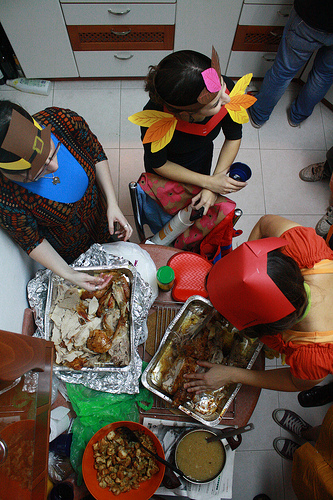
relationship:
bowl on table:
[80, 422, 164, 498] [17, 243, 264, 498]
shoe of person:
[271, 434, 298, 458] [266, 403, 322, 496]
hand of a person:
[181, 359, 232, 395] [176, 212, 317, 396]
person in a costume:
[136, 48, 249, 217] [126, 43, 256, 154]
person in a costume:
[0, 95, 131, 291] [0, 105, 107, 252]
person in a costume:
[176, 212, 317, 396] [204, 225, 321, 383]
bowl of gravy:
[170, 428, 225, 483] [175, 431, 223, 479]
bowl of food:
[80, 422, 164, 498] [96, 430, 143, 485]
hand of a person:
[104, 205, 132, 240] [0, 95, 131, 291]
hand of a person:
[69, 271, 115, 292] [0, 95, 131, 291]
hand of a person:
[207, 166, 248, 193] [136, 48, 249, 217]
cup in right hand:
[214, 158, 263, 176] [205, 166, 246, 195]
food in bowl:
[101, 440, 141, 481] [80, 422, 164, 498]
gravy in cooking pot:
[175, 431, 223, 479] [171, 419, 255, 480]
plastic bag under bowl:
[70, 382, 143, 422] [85, 429, 163, 498]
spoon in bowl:
[114, 425, 183, 477] [80, 422, 164, 498]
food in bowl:
[98, 431, 157, 484] [80, 417, 168, 492]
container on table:
[156, 265, 176, 291] [23, 240, 267, 447]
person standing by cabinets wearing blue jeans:
[253, 6, 323, 122] [254, 10, 322, 120]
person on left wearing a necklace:
[0, 95, 131, 291] [42, 167, 65, 186]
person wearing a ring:
[136, 48, 249, 217] [225, 187, 232, 194]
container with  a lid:
[153, 263, 176, 290] [156, 265, 174, 281]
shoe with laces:
[271, 402, 309, 440] [283, 414, 301, 429]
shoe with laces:
[271, 434, 298, 458] [286, 446, 298, 453]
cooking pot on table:
[175, 426, 255, 485] [50, 244, 265, 498]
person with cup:
[136, 48, 249, 217] [214, 158, 263, 176]